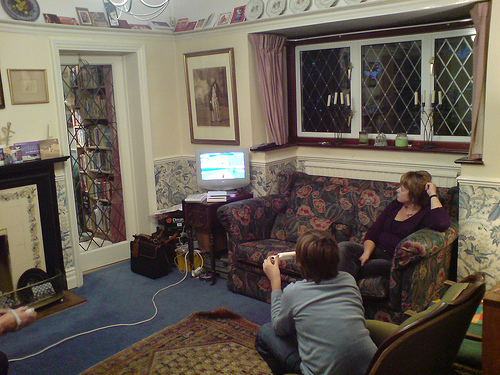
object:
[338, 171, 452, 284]
woman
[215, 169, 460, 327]
couch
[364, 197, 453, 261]
shirt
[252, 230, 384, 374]
person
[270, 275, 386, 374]
shirt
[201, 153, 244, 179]
screen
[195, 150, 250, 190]
television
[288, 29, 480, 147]
window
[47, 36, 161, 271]
door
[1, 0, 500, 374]
room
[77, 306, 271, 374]
rug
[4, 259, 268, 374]
floor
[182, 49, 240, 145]
picture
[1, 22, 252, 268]
wall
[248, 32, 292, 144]
curtains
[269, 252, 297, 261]
controller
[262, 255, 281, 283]
hands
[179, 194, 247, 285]
table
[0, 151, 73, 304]
fireplace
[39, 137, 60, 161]
cards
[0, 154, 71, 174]
mantle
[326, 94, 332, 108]
candles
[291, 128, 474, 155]
window frame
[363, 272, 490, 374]
back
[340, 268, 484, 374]
chair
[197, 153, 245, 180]
game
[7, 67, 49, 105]
plaque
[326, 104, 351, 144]
candle holder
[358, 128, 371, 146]
candle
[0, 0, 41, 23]
plate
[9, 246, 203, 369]
cord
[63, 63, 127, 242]
book cases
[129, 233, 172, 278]
bag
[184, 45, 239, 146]
frame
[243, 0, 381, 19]
dishes